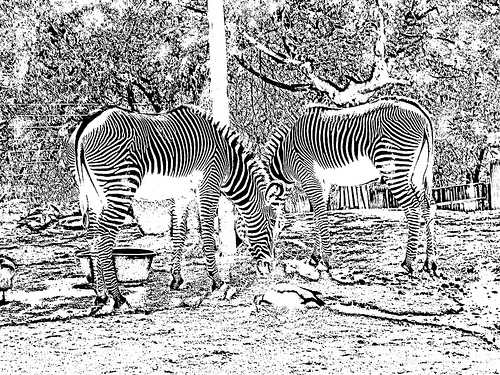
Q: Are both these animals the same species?
A: Yes, all the animals are zebras.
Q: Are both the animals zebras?
A: Yes, all the animals are zebras.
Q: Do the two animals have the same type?
A: Yes, all the animals are zebras.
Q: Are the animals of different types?
A: No, all the animals are zebras.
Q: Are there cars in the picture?
A: No, there are no cars.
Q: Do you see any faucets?
A: No, there are no faucets.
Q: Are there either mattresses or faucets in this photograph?
A: No, there are no faucets or mattresses.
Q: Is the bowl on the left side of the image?
A: Yes, the bowl is on the left of the image.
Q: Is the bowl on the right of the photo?
A: No, the bowl is on the left of the image.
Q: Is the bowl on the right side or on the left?
A: The bowl is on the left of the image.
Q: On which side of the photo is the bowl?
A: The bowl is on the left of the image.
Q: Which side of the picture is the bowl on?
A: The bowl is on the left of the image.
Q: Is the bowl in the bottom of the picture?
A: Yes, the bowl is in the bottom of the image.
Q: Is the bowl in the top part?
A: No, the bowl is in the bottom of the image.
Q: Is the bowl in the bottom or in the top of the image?
A: The bowl is in the bottom of the image.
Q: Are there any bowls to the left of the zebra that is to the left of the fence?
A: Yes, there is a bowl to the left of the zebra.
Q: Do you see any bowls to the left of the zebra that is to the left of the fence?
A: Yes, there is a bowl to the left of the zebra.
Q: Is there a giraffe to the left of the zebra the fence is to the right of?
A: No, there is a bowl to the left of the zebra.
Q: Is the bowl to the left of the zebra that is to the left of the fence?
A: Yes, the bowl is to the left of the zebra.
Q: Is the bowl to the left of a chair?
A: No, the bowl is to the left of the zebra.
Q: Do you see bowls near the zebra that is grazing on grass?
A: Yes, there is a bowl near the zebra.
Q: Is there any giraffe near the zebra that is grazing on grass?
A: No, there is a bowl near the zebra.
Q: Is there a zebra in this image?
A: Yes, there is a zebra.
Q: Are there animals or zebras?
A: Yes, there is a zebra.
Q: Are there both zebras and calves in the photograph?
A: No, there is a zebra but no calves.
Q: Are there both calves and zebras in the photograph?
A: No, there is a zebra but no calves.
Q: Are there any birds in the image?
A: No, there are no birds.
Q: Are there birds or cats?
A: No, there are no birds or cats.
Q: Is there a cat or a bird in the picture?
A: No, there are no birds or cats.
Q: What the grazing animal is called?
A: The animal is a zebra.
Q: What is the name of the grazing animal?
A: The animal is a zebra.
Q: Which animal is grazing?
A: The animal is a zebra.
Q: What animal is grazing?
A: The animal is a zebra.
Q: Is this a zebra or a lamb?
A: This is a zebra.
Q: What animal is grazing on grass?
A: The zebra is grazing on grass.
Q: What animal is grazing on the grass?
A: The zebra is grazing on grass.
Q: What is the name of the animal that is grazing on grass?
A: The animal is a zebra.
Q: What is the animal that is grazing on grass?
A: The animal is a zebra.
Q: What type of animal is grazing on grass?
A: The animal is a zebra.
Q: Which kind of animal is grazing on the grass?
A: The animal is a zebra.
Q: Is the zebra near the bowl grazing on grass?
A: Yes, the zebra is grazing on grass.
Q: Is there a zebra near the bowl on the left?
A: Yes, there is a zebra near the bowl.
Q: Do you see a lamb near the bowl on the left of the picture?
A: No, there is a zebra near the bowl.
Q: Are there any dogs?
A: No, there are no dogs.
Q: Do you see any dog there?
A: No, there are no dogs.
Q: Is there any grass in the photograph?
A: Yes, there is grass.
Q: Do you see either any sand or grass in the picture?
A: Yes, there is grass.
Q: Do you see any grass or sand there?
A: Yes, there is grass.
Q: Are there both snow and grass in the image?
A: No, there is grass but no snow.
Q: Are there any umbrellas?
A: No, there are no umbrellas.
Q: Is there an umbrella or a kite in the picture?
A: No, there are no umbrellas or kites.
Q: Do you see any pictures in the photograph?
A: No, there are no pictures.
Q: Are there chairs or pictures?
A: No, there are no pictures or chairs.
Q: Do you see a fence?
A: Yes, there is a fence.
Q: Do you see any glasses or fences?
A: Yes, there is a fence.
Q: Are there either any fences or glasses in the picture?
A: Yes, there is a fence.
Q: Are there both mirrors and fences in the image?
A: No, there is a fence but no mirrors.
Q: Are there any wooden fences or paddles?
A: Yes, there is a wood fence.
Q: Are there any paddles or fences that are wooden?
A: Yes, the fence is wooden.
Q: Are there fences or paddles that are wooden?
A: Yes, the fence is wooden.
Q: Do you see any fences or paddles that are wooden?
A: Yes, the fence is wooden.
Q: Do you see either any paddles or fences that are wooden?
A: Yes, the fence is wooden.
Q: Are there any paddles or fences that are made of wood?
A: Yes, the fence is made of wood.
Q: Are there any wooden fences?
A: Yes, there is a wood fence.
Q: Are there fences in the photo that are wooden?
A: Yes, there is a fence that is wooden.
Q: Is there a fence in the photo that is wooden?
A: Yes, there is a fence that is wooden.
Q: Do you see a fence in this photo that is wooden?
A: Yes, there is a fence that is wooden.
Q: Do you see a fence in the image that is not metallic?
A: Yes, there is a wooden fence.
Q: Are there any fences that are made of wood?
A: Yes, there is a fence that is made of wood.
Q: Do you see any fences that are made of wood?
A: Yes, there is a fence that is made of wood.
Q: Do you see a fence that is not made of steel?
A: Yes, there is a fence that is made of wood.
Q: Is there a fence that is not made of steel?
A: Yes, there is a fence that is made of wood.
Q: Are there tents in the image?
A: No, there are no tents.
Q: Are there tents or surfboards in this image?
A: No, there are no tents or surfboards.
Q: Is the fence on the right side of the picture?
A: Yes, the fence is on the right of the image.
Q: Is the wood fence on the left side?
A: No, the fence is on the right of the image.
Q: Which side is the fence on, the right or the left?
A: The fence is on the right of the image.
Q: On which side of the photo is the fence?
A: The fence is on the right of the image.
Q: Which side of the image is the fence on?
A: The fence is on the right of the image.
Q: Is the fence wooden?
A: Yes, the fence is wooden.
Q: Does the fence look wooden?
A: Yes, the fence is wooden.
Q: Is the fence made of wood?
A: Yes, the fence is made of wood.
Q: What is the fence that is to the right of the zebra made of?
A: The fence is made of wood.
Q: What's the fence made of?
A: The fence is made of wood.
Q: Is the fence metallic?
A: No, the fence is wooden.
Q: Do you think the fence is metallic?
A: No, the fence is wooden.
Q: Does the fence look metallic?
A: No, the fence is wooden.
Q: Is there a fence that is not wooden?
A: No, there is a fence but it is wooden.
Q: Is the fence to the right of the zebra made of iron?
A: No, the fence is made of wood.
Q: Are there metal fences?
A: No, there is a fence but it is made of wood.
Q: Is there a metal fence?
A: No, there is a fence but it is made of wood.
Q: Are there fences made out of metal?
A: No, there is a fence but it is made of wood.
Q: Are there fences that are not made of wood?
A: No, there is a fence but it is made of wood.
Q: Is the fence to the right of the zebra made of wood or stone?
A: The fence is made of wood.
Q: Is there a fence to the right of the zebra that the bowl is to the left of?
A: Yes, there is a fence to the right of the zebra.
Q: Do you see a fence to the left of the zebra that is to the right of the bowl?
A: No, the fence is to the right of the zebra.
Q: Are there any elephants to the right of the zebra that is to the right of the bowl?
A: No, there is a fence to the right of the zebra.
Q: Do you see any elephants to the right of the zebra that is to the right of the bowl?
A: No, there is a fence to the right of the zebra.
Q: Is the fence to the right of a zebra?
A: Yes, the fence is to the right of a zebra.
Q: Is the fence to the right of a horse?
A: No, the fence is to the right of a zebra.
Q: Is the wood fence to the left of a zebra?
A: No, the fence is to the right of a zebra.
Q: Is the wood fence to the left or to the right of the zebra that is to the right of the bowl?
A: The fence is to the right of the zebra.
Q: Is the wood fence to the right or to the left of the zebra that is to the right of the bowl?
A: The fence is to the right of the zebra.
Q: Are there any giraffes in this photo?
A: No, there are no giraffes.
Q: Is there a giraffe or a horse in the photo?
A: No, there are no giraffes or horses.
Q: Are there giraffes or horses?
A: No, there are no giraffes or horses.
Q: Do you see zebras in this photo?
A: Yes, there is a zebra.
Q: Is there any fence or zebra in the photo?
A: Yes, there is a zebra.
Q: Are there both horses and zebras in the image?
A: No, there is a zebra but no horses.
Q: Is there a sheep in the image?
A: No, there is no sheep.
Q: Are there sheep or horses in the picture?
A: No, there are no sheep or horses.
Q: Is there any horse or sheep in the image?
A: No, there are no sheep or horses.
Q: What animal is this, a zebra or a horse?
A: This is a zebra.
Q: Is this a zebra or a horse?
A: This is a zebra.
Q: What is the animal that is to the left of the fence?
A: The animal is a zebra.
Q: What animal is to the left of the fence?
A: The animal is a zebra.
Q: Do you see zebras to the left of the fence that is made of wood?
A: Yes, there is a zebra to the left of the fence.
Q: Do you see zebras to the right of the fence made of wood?
A: No, the zebra is to the left of the fence.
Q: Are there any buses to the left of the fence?
A: No, there is a zebra to the left of the fence.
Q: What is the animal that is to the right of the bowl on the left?
A: The animal is a zebra.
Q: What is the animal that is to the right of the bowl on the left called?
A: The animal is a zebra.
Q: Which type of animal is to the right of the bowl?
A: The animal is a zebra.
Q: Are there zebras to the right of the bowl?
A: Yes, there is a zebra to the right of the bowl.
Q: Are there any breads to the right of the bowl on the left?
A: No, there is a zebra to the right of the bowl.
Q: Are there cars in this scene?
A: No, there are no cars.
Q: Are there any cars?
A: No, there are no cars.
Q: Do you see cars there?
A: No, there are no cars.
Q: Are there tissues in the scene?
A: No, there are no tissues.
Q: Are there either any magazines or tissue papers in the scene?
A: No, there are no tissue papers or magazines.